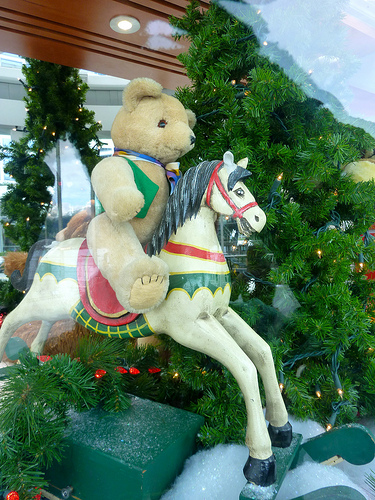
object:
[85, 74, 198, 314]
teddy bear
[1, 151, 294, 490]
rocking horse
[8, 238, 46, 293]
tail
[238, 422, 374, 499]
base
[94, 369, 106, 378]
light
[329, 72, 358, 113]
ground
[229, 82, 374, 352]
tree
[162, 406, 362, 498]
snow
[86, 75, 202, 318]
bear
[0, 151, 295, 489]
horse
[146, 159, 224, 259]
mane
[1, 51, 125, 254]
window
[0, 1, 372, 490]
christmas tree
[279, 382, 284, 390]
light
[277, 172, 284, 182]
light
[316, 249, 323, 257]
light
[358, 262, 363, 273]
light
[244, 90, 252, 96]
light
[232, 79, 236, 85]
light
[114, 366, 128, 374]
light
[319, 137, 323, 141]
lights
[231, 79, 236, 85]
lights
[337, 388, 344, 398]
lights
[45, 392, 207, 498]
box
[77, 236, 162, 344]
saddle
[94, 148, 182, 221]
vest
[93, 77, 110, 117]
sunlight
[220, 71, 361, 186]
greenery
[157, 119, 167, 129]
eyes